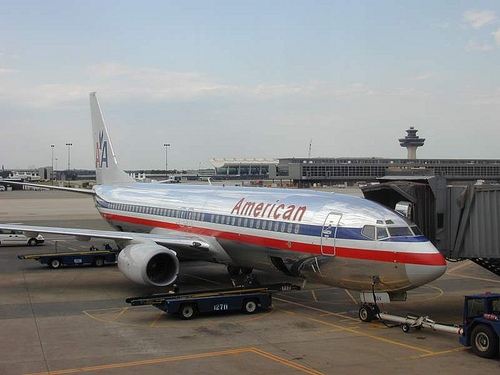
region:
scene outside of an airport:
[6, 83, 498, 365]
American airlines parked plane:
[4, 91, 451, 349]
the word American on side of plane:
[221, 195, 316, 229]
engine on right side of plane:
[111, 241, 188, 293]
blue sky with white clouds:
[12, 8, 493, 88]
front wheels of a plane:
[354, 305, 383, 327]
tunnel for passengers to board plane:
[438, 168, 498, 270]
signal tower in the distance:
[398, 121, 424, 161]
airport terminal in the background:
[279, 148, 498, 183]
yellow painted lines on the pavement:
[44, 337, 344, 374]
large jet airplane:
[30, 86, 477, 343]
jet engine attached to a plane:
[6, 214, 242, 303]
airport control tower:
[377, 122, 442, 161]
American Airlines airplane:
[46, 112, 475, 341]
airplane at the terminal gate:
[14, 110, 499, 332]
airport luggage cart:
[116, 274, 313, 321]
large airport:
[118, 144, 498, 202]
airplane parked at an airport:
[17, 110, 497, 324]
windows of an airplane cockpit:
[340, 212, 428, 252]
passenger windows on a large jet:
[90, 186, 355, 256]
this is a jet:
[98, 189, 418, 309]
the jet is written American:
[231, 198, 310, 220]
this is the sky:
[173, 6, 375, 75]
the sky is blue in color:
[151, 7, 259, 38]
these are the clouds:
[152, 72, 200, 91]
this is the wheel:
[358, 306, 370, 323]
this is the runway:
[50, 322, 217, 368]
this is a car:
[1, 232, 21, 246]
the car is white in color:
[3, 236, 17, 243]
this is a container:
[438, 181, 499, 249]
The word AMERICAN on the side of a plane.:
[227, 194, 307, 221]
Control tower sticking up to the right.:
[394, 126, 426, 157]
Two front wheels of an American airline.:
[357, 304, 381, 324]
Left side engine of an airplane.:
[115, 239, 181, 289]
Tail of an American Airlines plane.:
[87, 92, 135, 182]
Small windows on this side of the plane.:
[106, 201, 299, 234]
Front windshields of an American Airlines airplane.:
[360, 223, 423, 245]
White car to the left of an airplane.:
[0, 222, 43, 243]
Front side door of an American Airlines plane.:
[318, 210, 340, 257]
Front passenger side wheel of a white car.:
[25, 236, 36, 246]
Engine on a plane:
[113, 235, 196, 294]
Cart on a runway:
[119, 280, 287, 320]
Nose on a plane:
[373, 209, 457, 298]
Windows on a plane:
[351, 221, 428, 241]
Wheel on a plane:
[349, 296, 383, 329]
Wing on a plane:
[23, 208, 253, 269]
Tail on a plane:
[14, 108, 192, 195]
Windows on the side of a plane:
[98, 198, 387, 244]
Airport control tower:
[389, 128, 438, 158]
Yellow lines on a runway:
[56, 303, 183, 373]